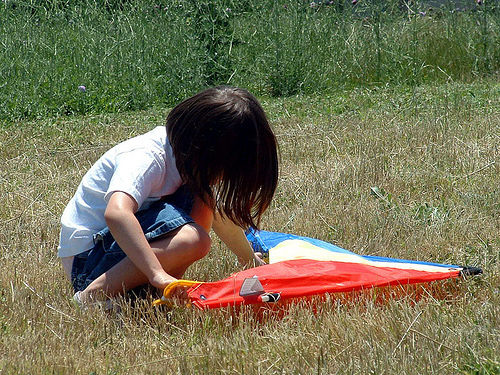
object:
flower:
[73, 80, 89, 94]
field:
[0, 76, 497, 373]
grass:
[0, 79, 498, 372]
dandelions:
[360, 152, 464, 254]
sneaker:
[64, 287, 121, 316]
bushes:
[3, 0, 498, 123]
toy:
[153, 225, 482, 315]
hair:
[165, 83, 284, 229]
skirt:
[69, 182, 226, 292]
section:
[242, 221, 462, 272]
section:
[187, 256, 464, 308]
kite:
[151, 226, 483, 310]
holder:
[152, 269, 213, 307]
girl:
[59, 84, 283, 318]